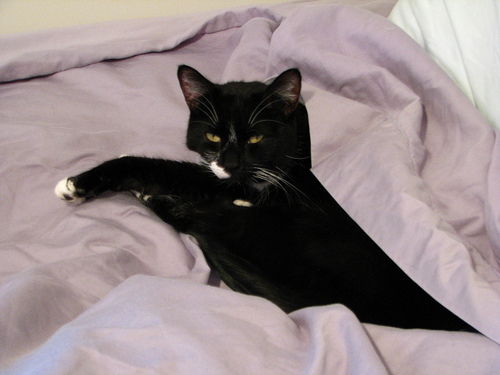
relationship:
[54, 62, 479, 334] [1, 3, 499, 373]
cat laying on blanket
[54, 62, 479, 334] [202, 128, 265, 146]
cat has eyes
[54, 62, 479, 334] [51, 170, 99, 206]
cat has paw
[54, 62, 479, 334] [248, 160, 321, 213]
cat has whiskers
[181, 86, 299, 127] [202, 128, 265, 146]
whiskers above eyes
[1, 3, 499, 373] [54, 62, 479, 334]
blanket covering cat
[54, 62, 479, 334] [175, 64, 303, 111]
cat has ears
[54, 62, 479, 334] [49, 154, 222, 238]
cat has legs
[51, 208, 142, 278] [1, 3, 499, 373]
wrinkles on blanket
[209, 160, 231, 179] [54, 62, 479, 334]
spot on cat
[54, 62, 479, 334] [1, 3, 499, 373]
cat on blanket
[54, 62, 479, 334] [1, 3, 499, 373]
cat laying in blanket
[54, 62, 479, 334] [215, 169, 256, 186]
cat has mouth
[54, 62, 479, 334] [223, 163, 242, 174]
cat has nose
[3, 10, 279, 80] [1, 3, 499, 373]
fold in blanket